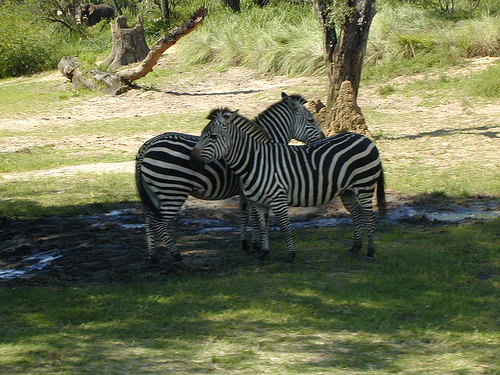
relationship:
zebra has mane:
[212, 109, 391, 257] [229, 115, 273, 143]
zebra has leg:
[212, 109, 391, 257] [361, 187, 391, 270]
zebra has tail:
[212, 109, 391, 257] [379, 144, 385, 214]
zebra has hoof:
[212, 109, 391, 257] [284, 252, 298, 262]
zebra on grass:
[212, 109, 391, 257] [212, 33, 321, 79]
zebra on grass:
[125, 82, 312, 248] [212, 33, 321, 79]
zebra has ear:
[212, 109, 391, 257] [225, 114, 243, 125]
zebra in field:
[212, 109, 391, 257] [17, 76, 498, 362]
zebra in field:
[125, 82, 312, 248] [17, 76, 498, 362]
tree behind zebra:
[92, 11, 163, 72] [212, 109, 391, 257]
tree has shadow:
[327, 19, 367, 143] [397, 113, 500, 151]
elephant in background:
[72, 5, 119, 29] [12, 3, 488, 61]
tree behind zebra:
[327, 19, 367, 143] [212, 109, 391, 257]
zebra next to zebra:
[212, 109, 391, 257] [125, 82, 312, 248]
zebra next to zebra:
[125, 82, 312, 248] [212, 109, 391, 257]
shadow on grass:
[397, 113, 500, 151] [212, 33, 321, 79]